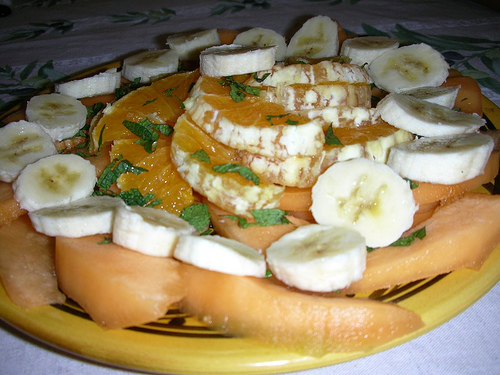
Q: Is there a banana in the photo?
A: Yes, there is a banana.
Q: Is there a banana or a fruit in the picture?
A: Yes, there is a banana.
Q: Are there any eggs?
A: No, there are no eggs.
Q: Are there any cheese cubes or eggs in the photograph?
A: No, there are no eggs or cheese cubes.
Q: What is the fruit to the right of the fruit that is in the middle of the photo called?
A: The fruit is a banana.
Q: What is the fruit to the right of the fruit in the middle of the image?
A: The fruit is a banana.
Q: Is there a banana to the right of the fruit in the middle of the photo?
A: Yes, there is a banana to the right of the fruit.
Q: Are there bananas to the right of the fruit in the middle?
A: Yes, there is a banana to the right of the fruit.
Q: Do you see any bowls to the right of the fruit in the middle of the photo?
A: No, there is a banana to the right of the fruit.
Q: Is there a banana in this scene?
A: Yes, there is a banana.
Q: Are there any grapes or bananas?
A: Yes, there is a banana.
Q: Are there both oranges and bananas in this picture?
A: Yes, there are both a banana and oranges.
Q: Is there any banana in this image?
A: Yes, there is a banana.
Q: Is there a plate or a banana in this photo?
A: Yes, there is a banana.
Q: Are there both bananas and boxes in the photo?
A: No, there is a banana but no boxes.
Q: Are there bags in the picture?
A: No, there are no bags.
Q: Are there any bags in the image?
A: No, there are no bags.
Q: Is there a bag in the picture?
A: No, there are no bags.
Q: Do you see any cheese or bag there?
A: No, there are no bags or cheese.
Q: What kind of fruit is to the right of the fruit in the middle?
A: The fruit is a banana.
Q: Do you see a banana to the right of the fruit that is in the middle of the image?
A: Yes, there is a banana to the right of the fruit.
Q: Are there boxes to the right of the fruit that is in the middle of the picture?
A: No, there is a banana to the right of the fruit.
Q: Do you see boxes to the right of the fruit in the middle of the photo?
A: No, there is a banana to the right of the fruit.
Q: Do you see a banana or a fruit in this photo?
A: Yes, there is a banana.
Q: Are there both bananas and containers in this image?
A: No, there is a banana but no containers.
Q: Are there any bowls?
A: No, there are no bowls.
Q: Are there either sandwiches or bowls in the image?
A: No, there are no bowls or sandwiches.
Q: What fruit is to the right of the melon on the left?
A: The fruit is a banana.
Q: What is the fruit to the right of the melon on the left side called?
A: The fruit is a banana.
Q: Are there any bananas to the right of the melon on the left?
A: Yes, there is a banana to the right of the melon.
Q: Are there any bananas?
A: Yes, there is a banana.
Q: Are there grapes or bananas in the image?
A: Yes, there is a banana.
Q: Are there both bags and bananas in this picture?
A: No, there is a banana but no bags.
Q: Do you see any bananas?
A: Yes, there is a banana.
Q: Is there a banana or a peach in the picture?
A: Yes, there is a banana.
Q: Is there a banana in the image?
A: Yes, there is a banana.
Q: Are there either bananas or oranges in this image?
A: Yes, there is a banana.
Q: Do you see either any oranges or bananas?
A: Yes, there is a banana.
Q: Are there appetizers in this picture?
A: No, there are no appetizers.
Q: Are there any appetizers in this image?
A: No, there are no appetizers.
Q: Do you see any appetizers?
A: No, there are no appetizers.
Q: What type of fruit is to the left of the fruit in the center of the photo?
A: The fruit is a banana.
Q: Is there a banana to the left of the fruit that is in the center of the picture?
A: Yes, there is a banana to the left of the fruit.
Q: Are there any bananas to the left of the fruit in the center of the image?
A: Yes, there is a banana to the left of the fruit.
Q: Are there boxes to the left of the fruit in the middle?
A: No, there is a banana to the left of the fruit.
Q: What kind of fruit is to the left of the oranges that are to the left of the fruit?
A: The fruit is a banana.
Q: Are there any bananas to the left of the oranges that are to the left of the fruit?
A: Yes, there is a banana to the left of the oranges.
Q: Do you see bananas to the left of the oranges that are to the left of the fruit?
A: Yes, there is a banana to the left of the oranges.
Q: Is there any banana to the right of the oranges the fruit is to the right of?
A: No, the banana is to the left of the oranges.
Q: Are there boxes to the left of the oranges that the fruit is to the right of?
A: No, there is a banana to the left of the oranges.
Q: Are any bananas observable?
A: Yes, there is a banana.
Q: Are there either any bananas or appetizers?
A: Yes, there is a banana.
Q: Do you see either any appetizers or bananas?
A: Yes, there is a banana.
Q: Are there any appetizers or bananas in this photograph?
A: Yes, there is a banana.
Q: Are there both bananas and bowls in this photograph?
A: No, there is a banana but no bowls.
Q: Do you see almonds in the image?
A: No, there are no almonds.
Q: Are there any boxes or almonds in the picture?
A: No, there are no almonds or boxes.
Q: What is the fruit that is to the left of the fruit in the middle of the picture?
A: The fruit is a banana.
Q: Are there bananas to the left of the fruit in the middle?
A: Yes, there is a banana to the left of the fruit.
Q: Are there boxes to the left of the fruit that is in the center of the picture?
A: No, there is a banana to the left of the fruit.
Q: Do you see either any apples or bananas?
A: Yes, there is a banana.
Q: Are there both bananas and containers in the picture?
A: No, there is a banana but no containers.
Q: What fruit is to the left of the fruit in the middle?
A: The fruit is a banana.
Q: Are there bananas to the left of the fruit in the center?
A: Yes, there is a banana to the left of the fruit.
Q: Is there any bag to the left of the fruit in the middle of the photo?
A: No, there is a banana to the left of the fruit.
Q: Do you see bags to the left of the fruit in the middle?
A: No, there is a banana to the left of the fruit.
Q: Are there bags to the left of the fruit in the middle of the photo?
A: No, there is a banana to the left of the fruit.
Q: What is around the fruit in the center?
A: The banana is around the fruit.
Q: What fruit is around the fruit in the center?
A: The fruit is a banana.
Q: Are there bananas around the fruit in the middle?
A: Yes, there is a banana around the fruit.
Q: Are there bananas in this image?
A: Yes, there is a banana.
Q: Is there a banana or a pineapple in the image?
A: Yes, there is a banana.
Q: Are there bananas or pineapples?
A: Yes, there is a banana.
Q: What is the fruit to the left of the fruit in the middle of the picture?
A: The fruit is a banana.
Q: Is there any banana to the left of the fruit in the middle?
A: Yes, there is a banana to the left of the fruit.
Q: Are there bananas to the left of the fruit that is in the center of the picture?
A: Yes, there is a banana to the left of the fruit.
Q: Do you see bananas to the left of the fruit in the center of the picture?
A: Yes, there is a banana to the left of the fruit.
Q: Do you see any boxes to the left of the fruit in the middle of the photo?
A: No, there is a banana to the left of the fruit.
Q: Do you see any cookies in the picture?
A: No, there are no cookies.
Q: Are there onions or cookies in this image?
A: No, there are no cookies or onions.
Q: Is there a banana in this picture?
A: Yes, there is a banana.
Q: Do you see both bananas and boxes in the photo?
A: No, there is a banana but no boxes.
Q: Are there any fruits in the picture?
A: Yes, there is a fruit.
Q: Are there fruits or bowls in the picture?
A: Yes, there is a fruit.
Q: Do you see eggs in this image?
A: No, there are no eggs.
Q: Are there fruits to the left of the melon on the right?
A: Yes, there is a fruit to the left of the melon.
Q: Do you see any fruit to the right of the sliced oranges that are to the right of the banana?
A: Yes, there is a fruit to the right of the oranges.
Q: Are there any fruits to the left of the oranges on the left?
A: No, the fruit is to the right of the oranges.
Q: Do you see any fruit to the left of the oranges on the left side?
A: No, the fruit is to the right of the oranges.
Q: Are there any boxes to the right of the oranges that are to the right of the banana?
A: No, there is a fruit to the right of the oranges.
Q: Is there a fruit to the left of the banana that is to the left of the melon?
A: Yes, there is a fruit to the left of the banana.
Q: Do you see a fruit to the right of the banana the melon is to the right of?
A: No, the fruit is to the left of the banana.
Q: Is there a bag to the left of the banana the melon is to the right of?
A: No, there is a fruit to the left of the banana.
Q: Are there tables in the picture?
A: Yes, there is a table.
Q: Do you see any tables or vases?
A: Yes, there is a table.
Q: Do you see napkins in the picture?
A: No, there are no napkins.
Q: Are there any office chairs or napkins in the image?
A: No, there are no napkins or office chairs.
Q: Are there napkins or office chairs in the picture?
A: No, there are no napkins or office chairs.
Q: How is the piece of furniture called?
A: The piece of furniture is a table.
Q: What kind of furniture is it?
A: The piece of furniture is a table.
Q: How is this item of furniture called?
A: This is a table.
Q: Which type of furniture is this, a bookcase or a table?
A: This is a table.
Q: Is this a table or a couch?
A: This is a table.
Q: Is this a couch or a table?
A: This is a table.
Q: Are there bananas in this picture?
A: Yes, there is a banana.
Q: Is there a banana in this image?
A: Yes, there is a banana.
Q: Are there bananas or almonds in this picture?
A: Yes, there is a banana.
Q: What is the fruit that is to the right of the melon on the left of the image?
A: The fruit is a banana.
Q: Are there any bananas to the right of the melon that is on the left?
A: Yes, there is a banana to the right of the melon.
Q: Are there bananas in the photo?
A: Yes, there is a banana.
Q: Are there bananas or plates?
A: Yes, there is a banana.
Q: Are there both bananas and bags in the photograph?
A: No, there is a banana but no bags.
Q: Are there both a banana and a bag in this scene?
A: No, there is a banana but no bags.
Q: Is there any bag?
A: No, there are no bags.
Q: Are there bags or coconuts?
A: No, there are no bags or coconuts.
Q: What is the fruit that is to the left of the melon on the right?
A: The fruit is a banana.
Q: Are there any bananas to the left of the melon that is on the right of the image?
A: Yes, there is a banana to the left of the melon.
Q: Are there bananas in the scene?
A: Yes, there is a banana.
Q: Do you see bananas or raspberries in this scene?
A: Yes, there is a banana.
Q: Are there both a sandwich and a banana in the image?
A: No, there is a banana but no sandwiches.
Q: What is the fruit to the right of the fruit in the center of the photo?
A: The fruit is a banana.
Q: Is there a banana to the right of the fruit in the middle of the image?
A: Yes, there is a banana to the right of the fruit.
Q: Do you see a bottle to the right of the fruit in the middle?
A: No, there is a banana to the right of the fruit.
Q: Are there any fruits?
A: Yes, there is a fruit.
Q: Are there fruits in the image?
A: Yes, there is a fruit.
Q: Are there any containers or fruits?
A: Yes, there is a fruit.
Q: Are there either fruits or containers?
A: Yes, there is a fruit.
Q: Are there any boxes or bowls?
A: No, there are no bowls or boxes.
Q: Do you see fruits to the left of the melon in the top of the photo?
A: Yes, there is a fruit to the left of the melon.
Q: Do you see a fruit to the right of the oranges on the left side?
A: Yes, there is a fruit to the right of the oranges.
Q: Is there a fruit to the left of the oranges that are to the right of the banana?
A: No, the fruit is to the right of the oranges.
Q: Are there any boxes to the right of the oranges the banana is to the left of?
A: No, there is a fruit to the right of the oranges.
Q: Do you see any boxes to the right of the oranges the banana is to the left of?
A: No, there is a fruit to the right of the oranges.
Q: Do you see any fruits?
A: Yes, there is a fruit.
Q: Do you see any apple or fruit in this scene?
A: Yes, there is a fruit.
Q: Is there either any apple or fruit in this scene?
A: Yes, there is a fruit.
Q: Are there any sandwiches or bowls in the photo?
A: No, there are no bowls or sandwiches.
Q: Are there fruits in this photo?
A: Yes, there is a fruit.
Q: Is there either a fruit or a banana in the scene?
A: Yes, there is a fruit.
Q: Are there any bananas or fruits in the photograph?
A: Yes, there is a fruit.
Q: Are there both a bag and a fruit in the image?
A: No, there is a fruit but no bags.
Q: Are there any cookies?
A: No, there are no cookies.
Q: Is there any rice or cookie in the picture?
A: No, there are no cookies or rice.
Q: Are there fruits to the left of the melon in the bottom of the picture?
A: Yes, there is a fruit to the left of the melon.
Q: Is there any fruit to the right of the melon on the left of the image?
A: Yes, there is a fruit to the right of the melon.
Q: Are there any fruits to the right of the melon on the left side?
A: Yes, there is a fruit to the right of the melon.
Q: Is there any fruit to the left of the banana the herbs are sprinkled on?
A: Yes, there is a fruit to the left of the banana.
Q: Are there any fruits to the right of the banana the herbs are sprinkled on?
A: No, the fruit is to the left of the banana.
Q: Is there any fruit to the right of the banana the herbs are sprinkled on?
A: No, the fruit is to the left of the banana.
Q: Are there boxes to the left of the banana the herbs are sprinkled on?
A: No, there is a fruit to the left of the banana.